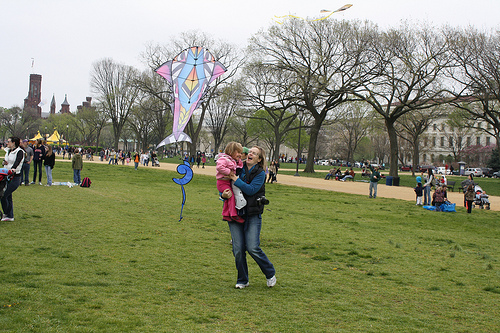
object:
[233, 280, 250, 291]
shoe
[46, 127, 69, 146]
tent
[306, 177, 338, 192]
road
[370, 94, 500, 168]
building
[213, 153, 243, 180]
coat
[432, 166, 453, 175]
vehicle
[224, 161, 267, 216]
vest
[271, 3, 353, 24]
yellow kite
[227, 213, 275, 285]
jean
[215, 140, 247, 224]
woman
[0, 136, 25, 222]
woman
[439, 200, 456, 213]
blue backback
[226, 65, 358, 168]
leaves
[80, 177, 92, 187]
backpack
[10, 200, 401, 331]
grass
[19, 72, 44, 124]
buildings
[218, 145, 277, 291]
she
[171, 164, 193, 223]
blue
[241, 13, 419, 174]
leaves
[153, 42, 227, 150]
flying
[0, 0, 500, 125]
sky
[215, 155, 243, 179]
jacket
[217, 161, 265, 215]
shirt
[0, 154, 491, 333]
field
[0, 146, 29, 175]
shirt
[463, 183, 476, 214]
stroller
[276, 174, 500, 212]
sidewalk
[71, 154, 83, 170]
jacket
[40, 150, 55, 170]
jacket